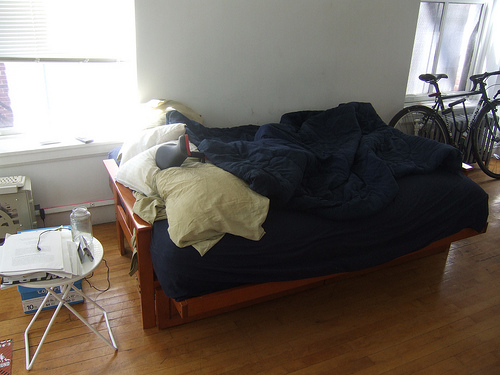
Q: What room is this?
A: Bedroom.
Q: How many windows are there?
A: Two.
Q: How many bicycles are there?
A: One.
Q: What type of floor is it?
A: Wood.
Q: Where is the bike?
A: By the window.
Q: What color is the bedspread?
A: Blue.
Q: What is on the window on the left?
A: Blinds.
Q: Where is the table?
A: Next to the bed.